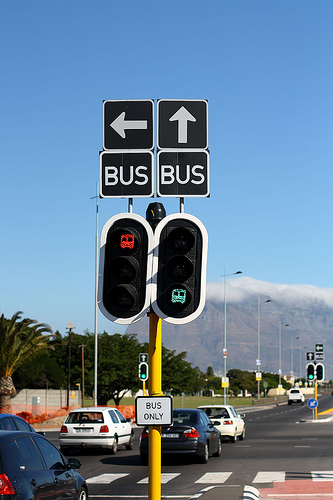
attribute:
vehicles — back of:
[0, 388, 322, 496]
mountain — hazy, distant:
[123, 274, 330, 379]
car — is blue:
[139, 408, 222, 461]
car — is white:
[197, 404, 244, 441]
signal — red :
[118, 234, 135, 250]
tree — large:
[11, 329, 199, 392]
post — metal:
[141, 312, 168, 498]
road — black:
[243, 398, 332, 465]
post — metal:
[221, 264, 227, 409]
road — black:
[33, 392, 332, 499]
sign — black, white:
[100, 92, 225, 189]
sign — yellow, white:
[65, 196, 253, 332]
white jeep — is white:
[282, 385, 311, 404]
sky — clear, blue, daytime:
[3, 5, 331, 103]